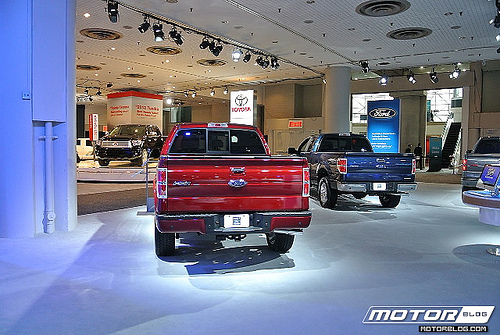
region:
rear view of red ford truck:
[152, 120, 310, 255]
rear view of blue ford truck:
[285, 131, 415, 206]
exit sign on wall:
[285, 116, 300, 126]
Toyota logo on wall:
[230, 91, 250, 111]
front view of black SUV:
[91, 121, 166, 166]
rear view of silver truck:
[460, 132, 497, 198]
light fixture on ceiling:
[375, 60, 460, 85]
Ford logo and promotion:
[365, 96, 396, 151]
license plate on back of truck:
[221, 211, 246, 223]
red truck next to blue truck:
[152, 120, 414, 256]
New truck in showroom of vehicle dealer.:
[150, 120, 310, 259]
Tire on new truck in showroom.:
[315, 176, 333, 209]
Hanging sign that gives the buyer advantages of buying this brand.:
[364, 98, 402, 154]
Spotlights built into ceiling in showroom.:
[375, 73, 417, 87]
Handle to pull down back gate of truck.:
[227, 165, 246, 173]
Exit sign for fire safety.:
[286, 118, 303, 129]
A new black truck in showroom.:
[95, 122, 168, 167]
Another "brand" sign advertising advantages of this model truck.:
[228, 88, 254, 125]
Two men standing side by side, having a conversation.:
[402, 141, 422, 171]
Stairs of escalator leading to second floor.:
[438, 115, 463, 169]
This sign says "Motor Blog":
[361, 291, 451, 318]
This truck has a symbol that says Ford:
[229, 172, 251, 192]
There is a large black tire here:
[321, 172, 344, 228]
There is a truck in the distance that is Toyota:
[106, 122, 138, 162]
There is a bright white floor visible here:
[335, 234, 365, 315]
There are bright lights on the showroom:
[375, 62, 402, 113]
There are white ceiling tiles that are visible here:
[458, 40, 463, 55]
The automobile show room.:
[90, 1, 497, 278]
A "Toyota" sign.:
[230, 93, 251, 115]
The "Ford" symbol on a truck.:
[223, 179, 248, 190]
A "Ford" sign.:
[365, 97, 400, 157]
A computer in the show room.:
[465, 161, 498, 198]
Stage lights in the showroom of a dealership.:
[103, 0, 321, 77]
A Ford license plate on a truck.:
[221, 213, 253, 233]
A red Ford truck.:
[152, 119, 314, 264]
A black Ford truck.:
[95, 117, 176, 167]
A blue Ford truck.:
[287, 131, 417, 211]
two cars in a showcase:
[152, 111, 413, 255]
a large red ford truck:
[102, 92, 309, 264]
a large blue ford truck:
[295, 129, 416, 219]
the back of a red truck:
[164, 162, 331, 223]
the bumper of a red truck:
[150, 208, 317, 236]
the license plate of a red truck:
[212, 213, 270, 240]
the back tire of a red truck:
[138, 226, 193, 257]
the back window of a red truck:
[167, 135, 272, 156]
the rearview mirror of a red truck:
[141, 138, 162, 166]